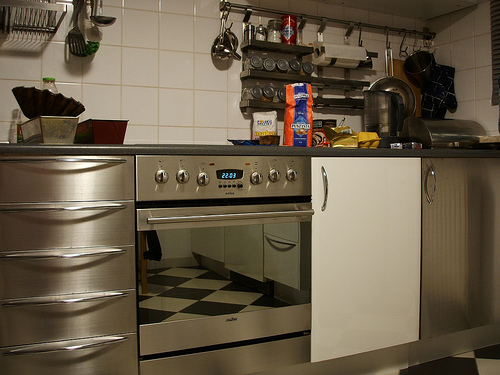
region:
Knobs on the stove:
[151, 163, 299, 192]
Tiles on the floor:
[389, 341, 498, 372]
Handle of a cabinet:
[313, 162, 334, 217]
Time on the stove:
[209, 163, 242, 183]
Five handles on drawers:
[2, 148, 130, 362]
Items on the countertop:
[226, 77, 428, 151]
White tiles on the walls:
[1, 1, 498, 145]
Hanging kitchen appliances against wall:
[209, 1, 463, 121]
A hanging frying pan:
[364, 39, 420, 121]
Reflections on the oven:
[134, 215, 314, 327]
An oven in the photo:
[137, 155, 297, 317]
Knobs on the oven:
[152, 159, 318, 190]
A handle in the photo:
[316, 157, 335, 207]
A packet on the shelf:
[270, 71, 324, 151]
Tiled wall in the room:
[101, 45, 205, 99]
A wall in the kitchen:
[98, 30, 204, 90]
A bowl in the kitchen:
[19, 84, 83, 116]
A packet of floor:
[249, 102, 279, 144]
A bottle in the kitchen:
[35, 64, 70, 96]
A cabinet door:
[426, 169, 488, 319]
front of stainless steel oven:
[130, 152, 315, 374]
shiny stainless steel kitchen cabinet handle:
[318, 163, 331, 214]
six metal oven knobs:
[143, 164, 301, 188]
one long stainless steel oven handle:
[141, 208, 317, 225]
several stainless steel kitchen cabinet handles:
[2, 150, 130, 367]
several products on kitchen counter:
[228, 78, 383, 148]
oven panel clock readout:
[212, 163, 245, 183]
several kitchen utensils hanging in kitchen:
[68, 2, 121, 67]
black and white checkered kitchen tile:
[139, 260, 294, 323]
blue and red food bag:
[281, 78, 316, 148]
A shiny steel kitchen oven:
[134, 150, 313, 372]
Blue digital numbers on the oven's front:
[216, 168, 239, 180]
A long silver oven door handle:
[148, 207, 316, 225]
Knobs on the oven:
[248, 165, 299, 187]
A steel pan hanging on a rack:
[366, 49, 417, 120]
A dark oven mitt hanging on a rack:
[419, 59, 462, 121]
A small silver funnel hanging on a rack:
[210, 30, 242, 62]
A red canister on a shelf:
[276, 12, 301, 46]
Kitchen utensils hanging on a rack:
[66, 0, 115, 67]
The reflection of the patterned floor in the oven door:
[131, 260, 303, 330]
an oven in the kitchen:
[128, 139, 312, 373]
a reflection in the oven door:
[141, 222, 306, 322]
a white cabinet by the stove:
[308, 152, 421, 352]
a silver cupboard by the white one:
[413, 152, 498, 344]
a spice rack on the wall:
[239, 14, 311, 114]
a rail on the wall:
[213, 2, 448, 42]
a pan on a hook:
[375, 44, 414, 122]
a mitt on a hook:
[409, 53, 464, 118]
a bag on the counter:
[278, 82, 313, 151]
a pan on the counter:
[75, 112, 130, 144]